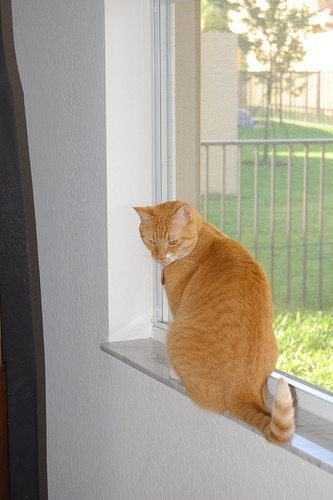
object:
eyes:
[147, 238, 178, 245]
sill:
[100, 321, 333, 473]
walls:
[55, 358, 209, 499]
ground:
[236, 108, 255, 134]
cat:
[130, 199, 295, 446]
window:
[150, 0, 332, 422]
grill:
[236, 106, 260, 141]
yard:
[198, 46, 332, 395]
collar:
[160, 264, 170, 286]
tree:
[224, 0, 295, 167]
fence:
[239, 69, 332, 123]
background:
[202, 0, 331, 210]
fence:
[195, 141, 333, 310]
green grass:
[271, 311, 333, 398]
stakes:
[237, 92, 296, 167]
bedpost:
[4, 356, 40, 466]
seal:
[131, 308, 170, 346]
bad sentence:
[11, 319, 104, 359]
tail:
[232, 376, 296, 445]